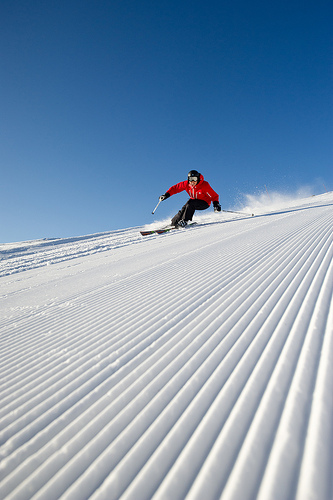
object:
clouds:
[244, 74, 293, 118]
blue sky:
[0, 0, 332, 246]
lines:
[2, 248, 318, 500]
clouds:
[147, 125, 256, 153]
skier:
[159, 170, 222, 228]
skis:
[140, 222, 198, 236]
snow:
[141, 316, 332, 498]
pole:
[214, 209, 254, 216]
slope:
[2, 266, 332, 499]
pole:
[152, 201, 161, 215]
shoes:
[177, 219, 187, 228]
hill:
[0, 189, 333, 500]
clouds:
[42, 29, 75, 64]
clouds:
[25, 94, 62, 129]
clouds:
[47, 133, 91, 170]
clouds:
[12, 167, 45, 195]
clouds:
[99, 67, 131, 95]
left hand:
[213, 201, 221, 213]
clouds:
[75, 171, 109, 201]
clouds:
[216, 34, 281, 66]